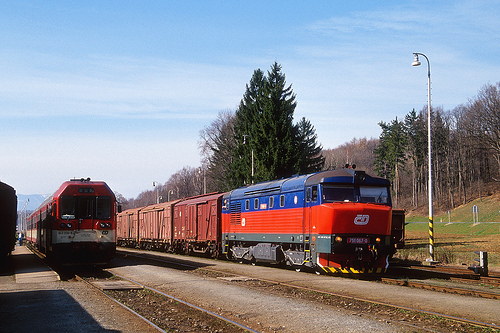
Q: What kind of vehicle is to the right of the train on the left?
A: The vehicle is a car.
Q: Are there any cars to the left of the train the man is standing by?
A: No, the car is to the right of the train.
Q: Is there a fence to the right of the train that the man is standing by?
A: No, there is a car to the right of the train.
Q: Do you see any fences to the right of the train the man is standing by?
A: No, there is a car to the right of the train.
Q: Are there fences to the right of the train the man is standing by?
A: No, there is a car to the right of the train.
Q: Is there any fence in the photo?
A: No, there are no fences.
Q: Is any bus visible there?
A: No, there are no buses.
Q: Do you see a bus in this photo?
A: No, there are no buses.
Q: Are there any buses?
A: No, there are no buses.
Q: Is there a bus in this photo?
A: No, there are no buses.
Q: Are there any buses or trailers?
A: No, there are no buses or trailers.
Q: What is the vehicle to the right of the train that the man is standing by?
A: The vehicle is a car.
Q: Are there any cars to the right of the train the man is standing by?
A: Yes, there is a car to the right of the train.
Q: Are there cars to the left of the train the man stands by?
A: No, the car is to the right of the train.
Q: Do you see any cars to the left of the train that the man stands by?
A: No, the car is to the right of the train.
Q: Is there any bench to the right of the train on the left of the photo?
A: No, there is a car to the right of the train.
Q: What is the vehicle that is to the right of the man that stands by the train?
A: The vehicle is a car.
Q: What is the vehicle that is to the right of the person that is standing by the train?
A: The vehicle is a car.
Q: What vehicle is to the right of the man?
A: The vehicle is a car.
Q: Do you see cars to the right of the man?
A: Yes, there is a car to the right of the man.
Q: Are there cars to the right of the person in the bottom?
A: Yes, there is a car to the right of the man.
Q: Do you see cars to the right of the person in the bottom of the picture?
A: Yes, there is a car to the right of the man.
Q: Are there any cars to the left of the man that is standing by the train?
A: No, the car is to the right of the man.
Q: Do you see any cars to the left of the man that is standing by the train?
A: No, the car is to the right of the man.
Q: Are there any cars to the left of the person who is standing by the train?
A: No, the car is to the right of the man.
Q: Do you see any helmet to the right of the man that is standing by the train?
A: No, there is a car to the right of the man.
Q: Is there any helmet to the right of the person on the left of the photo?
A: No, there is a car to the right of the man.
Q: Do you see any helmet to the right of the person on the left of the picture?
A: No, there is a car to the right of the man.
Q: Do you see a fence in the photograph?
A: No, there are no fences.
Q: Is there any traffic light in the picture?
A: No, there are no traffic lights.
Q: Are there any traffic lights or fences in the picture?
A: No, there are no traffic lights or fences.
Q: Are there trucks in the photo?
A: No, there are no trucks.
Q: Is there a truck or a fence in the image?
A: No, there are no trucks or fences.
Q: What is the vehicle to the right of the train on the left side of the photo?
A: The vehicle is a car.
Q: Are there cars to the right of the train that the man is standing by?
A: Yes, there is a car to the right of the train.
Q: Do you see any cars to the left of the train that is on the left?
A: No, the car is to the right of the train.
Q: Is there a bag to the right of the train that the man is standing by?
A: No, there is a car to the right of the train.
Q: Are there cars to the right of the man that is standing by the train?
A: Yes, there is a car to the right of the man.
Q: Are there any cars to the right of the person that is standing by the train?
A: Yes, there is a car to the right of the man.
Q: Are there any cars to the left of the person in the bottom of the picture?
A: No, the car is to the right of the man.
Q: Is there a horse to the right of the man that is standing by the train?
A: No, there is a car to the right of the man.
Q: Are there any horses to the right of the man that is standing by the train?
A: No, there is a car to the right of the man.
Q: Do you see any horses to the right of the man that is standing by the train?
A: No, there is a car to the right of the man.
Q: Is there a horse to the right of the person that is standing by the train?
A: No, there is a car to the right of the man.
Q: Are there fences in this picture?
A: No, there are no fences.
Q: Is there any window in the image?
A: Yes, there is a window.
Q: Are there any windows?
A: Yes, there is a window.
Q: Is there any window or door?
A: Yes, there is a window.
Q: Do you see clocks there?
A: No, there are no clocks.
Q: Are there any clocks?
A: No, there are no clocks.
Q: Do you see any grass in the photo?
A: Yes, there is grass.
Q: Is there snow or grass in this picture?
A: Yes, there is grass.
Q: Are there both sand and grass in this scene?
A: No, there is grass but no sand.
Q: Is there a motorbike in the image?
A: No, there are no motorcycles.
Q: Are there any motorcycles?
A: No, there are no motorcycles.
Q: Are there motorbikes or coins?
A: No, there are no motorbikes or coins.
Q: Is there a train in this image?
A: Yes, there is a train.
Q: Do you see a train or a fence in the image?
A: Yes, there is a train.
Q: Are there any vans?
A: No, there are no vans.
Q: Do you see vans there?
A: No, there are no vans.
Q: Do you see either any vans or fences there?
A: No, there are no vans or fences.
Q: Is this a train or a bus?
A: This is a train.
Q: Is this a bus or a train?
A: This is a train.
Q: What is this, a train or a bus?
A: This is a train.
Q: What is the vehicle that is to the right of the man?
A: The vehicle is a train.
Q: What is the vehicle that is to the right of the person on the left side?
A: The vehicle is a train.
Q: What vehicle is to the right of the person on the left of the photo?
A: The vehicle is a train.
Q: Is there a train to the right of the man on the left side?
A: Yes, there is a train to the right of the man.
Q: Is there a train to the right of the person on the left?
A: Yes, there is a train to the right of the man.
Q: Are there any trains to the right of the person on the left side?
A: Yes, there is a train to the right of the man.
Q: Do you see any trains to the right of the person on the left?
A: Yes, there is a train to the right of the man.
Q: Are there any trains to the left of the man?
A: No, the train is to the right of the man.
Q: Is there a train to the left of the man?
A: No, the train is to the right of the man.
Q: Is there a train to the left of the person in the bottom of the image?
A: No, the train is to the right of the man.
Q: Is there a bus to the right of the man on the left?
A: No, there is a train to the right of the man.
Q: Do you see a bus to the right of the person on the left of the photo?
A: No, there is a train to the right of the man.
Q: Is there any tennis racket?
A: No, there are no rackets.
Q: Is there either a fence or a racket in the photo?
A: No, there are no rackets or fences.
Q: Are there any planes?
A: No, there are no planes.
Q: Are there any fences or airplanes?
A: No, there are no airplanes or fences.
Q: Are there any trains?
A: Yes, there is a train.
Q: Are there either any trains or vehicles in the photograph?
A: Yes, there is a train.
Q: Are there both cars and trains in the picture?
A: Yes, there are both a train and a car.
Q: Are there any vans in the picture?
A: No, there are no vans.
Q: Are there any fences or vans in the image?
A: No, there are no vans or fences.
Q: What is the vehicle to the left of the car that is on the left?
A: The vehicle is a train.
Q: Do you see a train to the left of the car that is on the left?
A: Yes, there is a train to the left of the car.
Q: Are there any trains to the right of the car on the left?
A: No, the train is to the left of the car.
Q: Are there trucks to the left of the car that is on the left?
A: No, there is a train to the left of the car.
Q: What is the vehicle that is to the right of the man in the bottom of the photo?
A: The vehicle is a train.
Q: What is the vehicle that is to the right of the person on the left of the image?
A: The vehicle is a train.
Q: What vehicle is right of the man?
A: The vehicle is a train.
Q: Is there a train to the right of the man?
A: Yes, there is a train to the right of the man.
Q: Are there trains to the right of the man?
A: Yes, there is a train to the right of the man.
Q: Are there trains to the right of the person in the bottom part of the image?
A: Yes, there is a train to the right of the man.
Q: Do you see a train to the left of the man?
A: No, the train is to the right of the man.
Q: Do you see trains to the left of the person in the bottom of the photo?
A: No, the train is to the right of the man.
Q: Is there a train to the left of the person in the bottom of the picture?
A: No, the train is to the right of the man.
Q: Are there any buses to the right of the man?
A: No, there is a train to the right of the man.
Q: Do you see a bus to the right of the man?
A: No, there is a train to the right of the man.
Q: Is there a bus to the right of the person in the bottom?
A: No, there is a train to the right of the man.